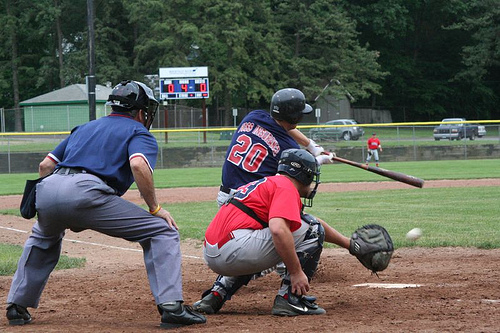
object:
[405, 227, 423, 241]
ball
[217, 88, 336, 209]
batter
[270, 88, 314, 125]
helmet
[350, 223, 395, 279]
catcher's mitt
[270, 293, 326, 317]
shoe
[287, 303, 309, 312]
logo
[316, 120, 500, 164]
fence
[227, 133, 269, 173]
20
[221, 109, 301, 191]
uniform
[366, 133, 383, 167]
man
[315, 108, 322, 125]
pole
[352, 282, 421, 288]
base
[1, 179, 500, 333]
dirt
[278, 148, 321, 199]
helmet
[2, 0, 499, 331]
baseball game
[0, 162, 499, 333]
field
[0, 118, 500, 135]
yellow band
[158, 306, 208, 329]
sneaker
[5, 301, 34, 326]
sneaker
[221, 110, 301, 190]
blue shirt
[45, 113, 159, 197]
blue shirt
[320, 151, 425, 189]
baseball bat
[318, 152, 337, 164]
hand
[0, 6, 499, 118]
forest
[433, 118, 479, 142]
truck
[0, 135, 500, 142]
road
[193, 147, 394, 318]
catcher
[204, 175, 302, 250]
shirt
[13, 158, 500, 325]
baseball field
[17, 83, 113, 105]
roof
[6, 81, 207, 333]
men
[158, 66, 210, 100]
scoreboard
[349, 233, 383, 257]
hand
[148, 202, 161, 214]
wrist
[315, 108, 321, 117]
sign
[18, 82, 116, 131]
building